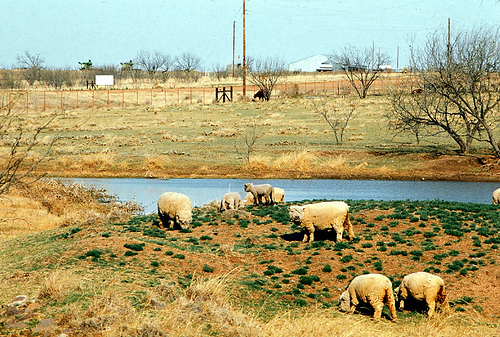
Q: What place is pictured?
A: It is a field.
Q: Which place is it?
A: It is a field.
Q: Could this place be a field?
A: Yes, it is a field.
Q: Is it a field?
A: Yes, it is a field.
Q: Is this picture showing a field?
A: Yes, it is showing a field.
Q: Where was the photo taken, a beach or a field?
A: It was taken at a field.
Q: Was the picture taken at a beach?
A: No, the picture was taken in a field.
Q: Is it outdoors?
A: Yes, it is outdoors.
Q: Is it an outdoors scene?
A: Yes, it is outdoors.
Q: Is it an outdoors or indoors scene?
A: It is outdoors.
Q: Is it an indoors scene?
A: No, it is outdoors.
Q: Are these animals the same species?
A: No, there are both sheep and cows.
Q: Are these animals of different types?
A: Yes, they are sheep and cows.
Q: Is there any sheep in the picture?
A: Yes, there is a sheep.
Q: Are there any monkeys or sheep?
A: Yes, there is a sheep.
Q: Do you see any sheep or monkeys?
A: Yes, there is a sheep.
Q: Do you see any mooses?
A: No, there are no mooses.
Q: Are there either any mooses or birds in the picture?
A: No, there are no mooses or birds.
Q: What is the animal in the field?
A: The animal is a sheep.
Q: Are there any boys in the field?
A: No, there is a sheep in the field.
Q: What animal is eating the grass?
A: The sheep is eating the grass.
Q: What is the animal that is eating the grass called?
A: The animal is a sheep.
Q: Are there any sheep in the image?
A: Yes, there is a sheep.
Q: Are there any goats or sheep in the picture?
A: Yes, there is a sheep.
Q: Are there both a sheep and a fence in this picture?
A: Yes, there are both a sheep and a fence.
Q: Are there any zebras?
A: No, there are no zebras.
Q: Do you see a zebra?
A: No, there are no zebras.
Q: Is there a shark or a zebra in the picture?
A: No, there are no zebras or sharks.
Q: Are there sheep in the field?
A: Yes, there is a sheep in the field.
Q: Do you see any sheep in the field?
A: Yes, there is a sheep in the field.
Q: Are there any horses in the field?
A: No, there is a sheep in the field.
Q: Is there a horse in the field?
A: No, there is a sheep in the field.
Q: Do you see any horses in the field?
A: No, there is a sheep in the field.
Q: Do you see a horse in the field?
A: No, there is a sheep in the field.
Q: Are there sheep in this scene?
A: Yes, there is a sheep.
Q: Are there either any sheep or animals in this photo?
A: Yes, there is a sheep.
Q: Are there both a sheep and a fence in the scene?
A: Yes, there are both a sheep and a fence.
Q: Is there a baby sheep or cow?
A: Yes, there is a baby sheep.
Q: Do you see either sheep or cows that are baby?
A: Yes, the sheep is a baby.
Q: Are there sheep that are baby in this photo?
A: Yes, there is a baby sheep.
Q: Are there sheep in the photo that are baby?
A: Yes, there is a sheep that is a baby.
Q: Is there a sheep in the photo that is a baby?
A: Yes, there is a sheep that is a baby.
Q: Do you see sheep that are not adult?
A: Yes, there is an baby sheep.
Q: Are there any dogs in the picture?
A: No, there are no dogs.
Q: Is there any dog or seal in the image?
A: No, there are no dogs or seals.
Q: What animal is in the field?
A: The animal is a sheep.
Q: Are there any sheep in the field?
A: Yes, there is a sheep in the field.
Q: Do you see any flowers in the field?
A: No, there is a sheep in the field.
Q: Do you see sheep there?
A: Yes, there is a sheep.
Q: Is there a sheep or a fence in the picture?
A: Yes, there is a sheep.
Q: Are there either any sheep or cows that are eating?
A: Yes, the sheep is eating.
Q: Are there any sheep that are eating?
A: Yes, there is a sheep that is eating.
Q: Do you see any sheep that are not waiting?
A: Yes, there is a sheep that is eating .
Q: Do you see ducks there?
A: No, there are no ducks.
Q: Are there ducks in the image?
A: No, there are no ducks.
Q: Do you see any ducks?
A: No, there are no ducks.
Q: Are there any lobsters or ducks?
A: No, there are no ducks or lobsters.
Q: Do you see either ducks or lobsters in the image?
A: No, there are no ducks or lobsters.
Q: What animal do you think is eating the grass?
A: The sheep is eating the grass.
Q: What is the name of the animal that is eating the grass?
A: The animal is a sheep.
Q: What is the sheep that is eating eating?
A: The sheep is eating grass.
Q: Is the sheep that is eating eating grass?
A: Yes, the sheep is eating grass.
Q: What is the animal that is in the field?
A: The animal is a sheep.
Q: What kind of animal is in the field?
A: The animal is a sheep.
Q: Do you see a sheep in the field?
A: Yes, there is a sheep in the field.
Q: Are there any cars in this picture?
A: No, there are no cars.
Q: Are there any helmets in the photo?
A: No, there are no helmets.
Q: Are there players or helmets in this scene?
A: No, there are no helmets or players.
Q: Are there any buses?
A: No, there are no buses.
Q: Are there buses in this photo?
A: No, there are no buses.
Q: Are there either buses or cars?
A: No, there are no buses or cars.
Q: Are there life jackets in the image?
A: No, there are no life jackets.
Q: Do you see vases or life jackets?
A: No, there are no life jackets or vases.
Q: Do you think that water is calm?
A: Yes, the water is calm.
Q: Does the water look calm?
A: Yes, the water is calm.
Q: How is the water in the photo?
A: The water is calm.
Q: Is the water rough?
A: No, the water is calm.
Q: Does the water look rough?
A: No, the water is calm.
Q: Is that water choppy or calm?
A: The water is calm.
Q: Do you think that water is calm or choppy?
A: The water is calm.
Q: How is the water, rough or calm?
A: The water is calm.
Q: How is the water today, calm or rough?
A: The water is calm.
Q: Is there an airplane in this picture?
A: No, there are no airplanes.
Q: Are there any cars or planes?
A: No, there are no planes or cars.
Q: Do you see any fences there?
A: Yes, there is a fence.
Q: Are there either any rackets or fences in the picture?
A: Yes, there is a fence.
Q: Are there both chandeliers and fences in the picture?
A: No, there is a fence but no chandeliers.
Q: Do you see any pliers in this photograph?
A: No, there are no pliers.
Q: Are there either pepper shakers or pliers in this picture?
A: No, there are no pliers or pepper shakers.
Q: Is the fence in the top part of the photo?
A: Yes, the fence is in the top of the image.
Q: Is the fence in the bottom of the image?
A: No, the fence is in the top of the image.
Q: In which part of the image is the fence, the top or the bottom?
A: The fence is in the top of the image.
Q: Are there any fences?
A: Yes, there is a fence.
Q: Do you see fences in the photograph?
A: Yes, there is a fence.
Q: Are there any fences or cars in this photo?
A: Yes, there is a fence.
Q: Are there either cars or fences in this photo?
A: Yes, there is a fence.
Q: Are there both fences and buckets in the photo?
A: No, there is a fence but no buckets.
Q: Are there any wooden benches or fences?
A: Yes, there is a wood fence.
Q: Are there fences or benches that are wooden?
A: Yes, the fence is wooden.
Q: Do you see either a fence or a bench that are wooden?
A: Yes, the fence is wooden.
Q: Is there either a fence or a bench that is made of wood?
A: Yes, the fence is made of wood.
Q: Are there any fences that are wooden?
A: Yes, there is a wood fence.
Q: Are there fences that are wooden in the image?
A: Yes, there is a wood fence.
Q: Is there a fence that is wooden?
A: Yes, there is a fence that is wooden.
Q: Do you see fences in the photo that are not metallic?
A: Yes, there is a wooden fence.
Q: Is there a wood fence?
A: Yes, there is a fence that is made of wood.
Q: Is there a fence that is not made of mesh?
A: Yes, there is a fence that is made of wood.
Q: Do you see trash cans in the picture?
A: No, there are no trash cans.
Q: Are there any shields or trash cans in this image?
A: No, there are no trash cans or shields.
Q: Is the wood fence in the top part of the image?
A: Yes, the fence is in the top of the image.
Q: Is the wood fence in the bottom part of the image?
A: No, the fence is in the top of the image.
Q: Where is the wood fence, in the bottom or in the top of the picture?
A: The fence is in the top of the image.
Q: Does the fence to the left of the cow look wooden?
A: Yes, the fence is wooden.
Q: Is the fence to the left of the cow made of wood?
A: Yes, the fence is made of wood.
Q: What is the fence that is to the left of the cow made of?
A: The fence is made of wood.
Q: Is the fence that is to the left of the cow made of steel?
A: No, the fence is made of wood.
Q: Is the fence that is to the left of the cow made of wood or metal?
A: The fence is made of wood.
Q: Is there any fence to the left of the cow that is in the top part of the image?
A: Yes, there is a fence to the left of the cow.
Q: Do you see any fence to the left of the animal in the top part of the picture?
A: Yes, there is a fence to the left of the cow.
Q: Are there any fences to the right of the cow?
A: No, the fence is to the left of the cow.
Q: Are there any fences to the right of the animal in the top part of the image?
A: No, the fence is to the left of the cow.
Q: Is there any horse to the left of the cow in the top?
A: No, there is a fence to the left of the cow.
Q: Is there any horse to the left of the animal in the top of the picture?
A: No, there is a fence to the left of the cow.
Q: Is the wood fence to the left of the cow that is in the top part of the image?
A: Yes, the fence is to the left of the cow.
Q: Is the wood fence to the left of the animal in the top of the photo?
A: Yes, the fence is to the left of the cow.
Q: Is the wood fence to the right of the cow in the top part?
A: No, the fence is to the left of the cow.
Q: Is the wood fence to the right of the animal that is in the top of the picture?
A: No, the fence is to the left of the cow.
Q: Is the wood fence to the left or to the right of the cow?
A: The fence is to the left of the cow.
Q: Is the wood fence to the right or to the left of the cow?
A: The fence is to the left of the cow.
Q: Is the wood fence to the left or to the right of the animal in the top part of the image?
A: The fence is to the left of the cow.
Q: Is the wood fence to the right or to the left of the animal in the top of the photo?
A: The fence is to the left of the cow.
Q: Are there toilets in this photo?
A: No, there are no toilets.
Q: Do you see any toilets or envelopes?
A: No, there are no toilets or envelopes.